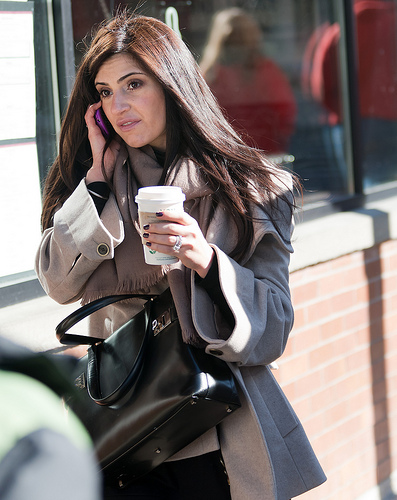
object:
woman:
[35, 14, 327, 500]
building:
[0, 0, 396, 499]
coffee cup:
[133, 185, 185, 266]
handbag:
[55, 286, 240, 495]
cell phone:
[94, 107, 110, 138]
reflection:
[198, 10, 297, 156]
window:
[70, 0, 397, 208]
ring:
[173, 234, 184, 251]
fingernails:
[155, 212, 164, 218]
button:
[96, 243, 110, 257]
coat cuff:
[62, 177, 124, 261]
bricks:
[306, 327, 367, 369]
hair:
[41, 0, 317, 267]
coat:
[34, 151, 328, 500]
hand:
[141, 210, 212, 274]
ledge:
[0, 197, 397, 355]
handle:
[54, 294, 160, 407]